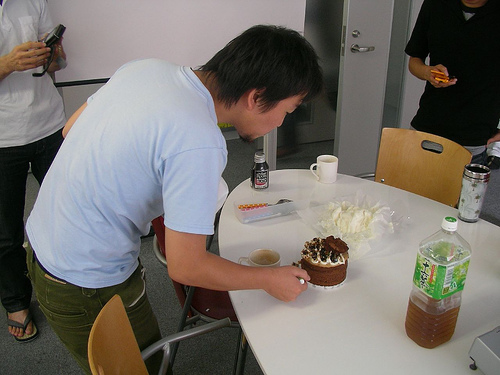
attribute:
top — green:
[440, 215, 455, 230]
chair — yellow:
[87, 291, 153, 373]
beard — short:
[243, 131, 261, 144]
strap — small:
[223, 209, 360, 340]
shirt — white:
[37, 48, 213, 292]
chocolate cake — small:
[260, 208, 369, 301]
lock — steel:
[348, 24, 365, 41]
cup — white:
[306, 153, 337, 182]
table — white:
[212, 163, 482, 373]